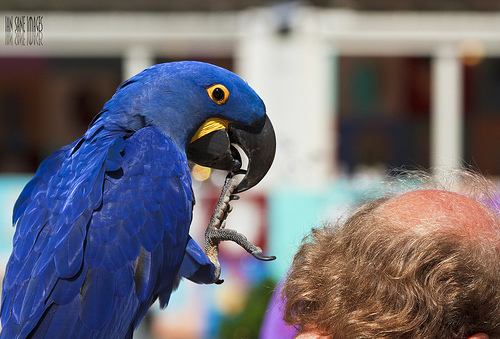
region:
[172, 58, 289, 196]
head of a parrot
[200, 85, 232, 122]
eye of a parrot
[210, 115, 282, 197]
mouth of a parrot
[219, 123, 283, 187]
peck of a parrot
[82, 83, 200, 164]
neck of a parrot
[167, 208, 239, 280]
wing of a parrot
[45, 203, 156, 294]
feather of a parrot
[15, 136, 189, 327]
body of a parrot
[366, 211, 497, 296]
hair of a person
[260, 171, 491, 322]
head of a person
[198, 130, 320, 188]
the beak of a blue parrot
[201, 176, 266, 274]
the claw of a blue parrot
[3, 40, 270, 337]
parrot with blue feathers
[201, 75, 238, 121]
parrots eye with yellow around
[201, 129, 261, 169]
parrot with mouth open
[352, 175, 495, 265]
man with balding spot in hair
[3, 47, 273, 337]
parrot with claw in mouth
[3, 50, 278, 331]
blue parrot on mans shoulder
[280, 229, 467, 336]
man with blonde hair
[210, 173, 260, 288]
parrot with gray claw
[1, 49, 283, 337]
A bird in the foreground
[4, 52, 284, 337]
A side view of a bird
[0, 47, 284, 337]
The bird is blue in color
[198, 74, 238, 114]
Yellow is around the bird's eye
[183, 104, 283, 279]
Bird is eating its feet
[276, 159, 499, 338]
The back of a person's head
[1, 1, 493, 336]
The background is blurred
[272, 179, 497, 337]
Person has light brown colored hair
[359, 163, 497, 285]
The top of the person's head is bald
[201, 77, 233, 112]
Bird's eye is black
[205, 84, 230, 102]
a blue parrot's yellow eye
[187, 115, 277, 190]
a blue parrot's beak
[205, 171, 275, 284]
a blue parrot's right foot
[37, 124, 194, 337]
a blue parrot's right wing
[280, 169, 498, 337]
the top of a balding man's head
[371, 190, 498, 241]
a man's bald spot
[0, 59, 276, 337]
a blue and yellow parrot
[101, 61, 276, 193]
a blue parrot's head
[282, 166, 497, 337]
hair on a balding man's head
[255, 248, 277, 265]
a blue parrot's talon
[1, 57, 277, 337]
Blue and yellow macau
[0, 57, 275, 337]
Macau with yellow eyes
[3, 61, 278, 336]
Parrot with claw in mouth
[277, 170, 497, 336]
Partially bald man's head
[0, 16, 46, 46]
Image credit from photographer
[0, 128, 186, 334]
Beautiful blue feathers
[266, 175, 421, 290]
Light blue out of focus background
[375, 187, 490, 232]
Sunburn on top of head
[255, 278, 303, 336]
Purple out of focus bacground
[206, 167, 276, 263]
Scales on bird talons